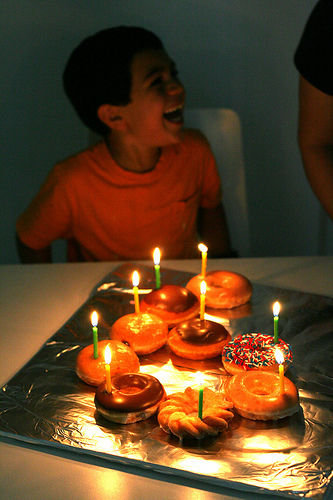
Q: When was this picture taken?
A: At a birthday party.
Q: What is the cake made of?
A: Donuts.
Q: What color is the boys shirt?
A: Orange.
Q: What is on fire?
A: Candles.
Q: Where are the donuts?
A: On the table.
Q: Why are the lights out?
A: To see the candle.